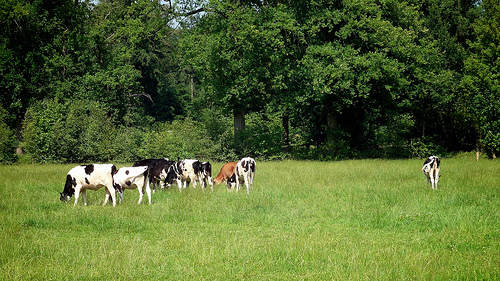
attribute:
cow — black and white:
[56, 163, 119, 208]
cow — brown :
[212, 160, 235, 186]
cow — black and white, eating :
[58, 164, 116, 206]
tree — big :
[171, 6, 301, 156]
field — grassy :
[4, 158, 497, 277]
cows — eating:
[26, 137, 269, 236]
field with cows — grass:
[42, 129, 451, 266]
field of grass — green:
[258, 162, 405, 256]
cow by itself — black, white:
[407, 143, 454, 196]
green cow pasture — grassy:
[261, 154, 403, 251]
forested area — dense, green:
[6, 3, 499, 154]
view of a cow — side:
[64, 162, 117, 208]